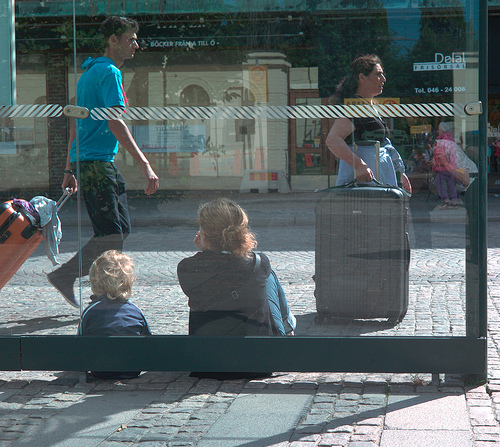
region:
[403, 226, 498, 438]
Brick city street.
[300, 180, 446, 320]
Very large suitcase.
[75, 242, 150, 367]
Blonde-headed child.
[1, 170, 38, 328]
Orange luggage.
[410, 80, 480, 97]
Telephone number on store window.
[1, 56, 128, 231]
Man pulling luggage wearing blue t-shirt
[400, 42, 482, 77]
Name of store printed on window.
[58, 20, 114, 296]
Man wearing dark pants.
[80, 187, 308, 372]
Woman and child sitting on pavement.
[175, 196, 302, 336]
Woman wearing a blue jacket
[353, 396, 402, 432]
part of a walkpath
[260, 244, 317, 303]
part of a glass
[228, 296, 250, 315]
part of a jacket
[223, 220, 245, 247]
hair of alady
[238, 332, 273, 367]
part of an edge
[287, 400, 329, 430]
part of a shade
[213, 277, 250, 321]
part of a handle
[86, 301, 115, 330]
part of a jacket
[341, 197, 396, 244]
part of a bag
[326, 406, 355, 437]
part of a shade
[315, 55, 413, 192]
a woman wheeling a suitcase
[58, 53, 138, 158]
a blue shirt on a man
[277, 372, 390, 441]
brick paved ground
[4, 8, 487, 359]
a glass partition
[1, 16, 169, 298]
a man pulling an orange suitcase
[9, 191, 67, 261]
clothes piled on an orange suitcase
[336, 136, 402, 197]
a pale blue skirt on a woan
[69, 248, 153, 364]
a child with blond hair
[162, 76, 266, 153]
arched windows reflected in a glass partition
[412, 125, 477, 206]
a person bending over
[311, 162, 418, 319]
The black rolling suitcase the lady is holding.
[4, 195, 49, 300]
The orange/red suitcase the man is rolling.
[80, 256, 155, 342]
The child sitting down.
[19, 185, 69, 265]
The sweaters hanging off of the orange/red suitcase.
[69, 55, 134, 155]
The blue shirt the man is wearing.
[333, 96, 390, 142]
The black top the lady is wearing.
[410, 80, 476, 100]
The telephone number on the glass.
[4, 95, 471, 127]
The white stripe design on the glass.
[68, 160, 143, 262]
The black pants the man is wearing.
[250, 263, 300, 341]
The jean pant leg the person sitting next to the child is wearing.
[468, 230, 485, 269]
edge of a window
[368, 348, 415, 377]
bottom of a glass window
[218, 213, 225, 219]
a woman's hair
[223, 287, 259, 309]
back of a woman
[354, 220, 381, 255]
section of a suite case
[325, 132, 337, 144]
part of a woman's elbow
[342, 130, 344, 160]
right arm of a woman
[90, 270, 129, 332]
a small child sitting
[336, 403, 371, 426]
section of a rocky surface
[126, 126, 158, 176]
right arm of a woman